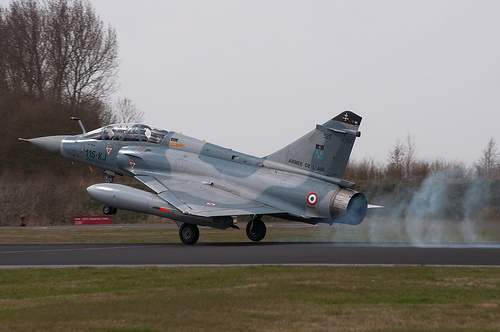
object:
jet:
[17, 109, 387, 247]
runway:
[70, 246, 188, 263]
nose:
[15, 129, 63, 155]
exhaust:
[387, 185, 491, 237]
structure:
[71, 215, 113, 226]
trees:
[385, 136, 418, 186]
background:
[379, 122, 500, 187]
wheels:
[244, 218, 268, 242]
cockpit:
[83, 120, 166, 141]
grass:
[80, 275, 141, 295]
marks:
[306, 192, 319, 206]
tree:
[3, 0, 121, 107]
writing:
[288, 158, 327, 174]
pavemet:
[181, 248, 233, 267]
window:
[103, 125, 148, 139]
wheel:
[177, 224, 200, 245]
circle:
[306, 191, 318, 205]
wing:
[129, 170, 288, 219]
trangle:
[133, 171, 286, 217]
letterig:
[85, 147, 107, 161]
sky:
[201, 26, 479, 98]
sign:
[72, 216, 113, 225]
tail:
[289, 110, 364, 169]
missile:
[84, 182, 235, 232]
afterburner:
[345, 192, 369, 228]